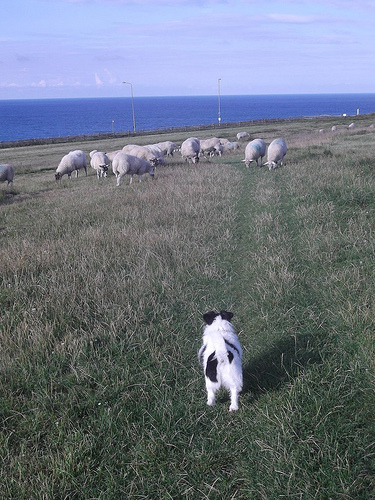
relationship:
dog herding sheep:
[176, 296, 272, 423] [53, 116, 289, 189]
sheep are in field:
[53, 116, 289, 189] [32, 185, 371, 298]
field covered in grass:
[32, 185, 371, 298] [280, 352, 347, 459]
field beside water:
[32, 185, 371, 298] [5, 92, 119, 142]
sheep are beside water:
[53, 116, 289, 189] [5, 92, 119, 142]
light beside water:
[213, 70, 231, 133] [5, 92, 119, 142]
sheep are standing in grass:
[53, 116, 289, 189] [280, 352, 347, 459]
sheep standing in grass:
[53, 116, 289, 189] [280, 352, 347, 459]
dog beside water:
[176, 296, 272, 423] [5, 92, 119, 142]